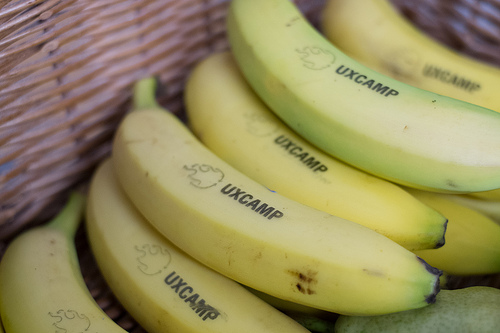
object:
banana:
[114, 76, 442, 313]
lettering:
[218, 183, 285, 221]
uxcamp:
[331, 63, 397, 103]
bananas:
[183, 55, 444, 252]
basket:
[0, 0, 232, 239]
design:
[295, 46, 339, 72]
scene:
[0, 0, 497, 333]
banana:
[229, 0, 499, 192]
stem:
[128, 74, 163, 109]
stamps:
[273, 134, 330, 174]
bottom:
[436, 217, 450, 251]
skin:
[204, 240, 275, 257]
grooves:
[53, 18, 139, 44]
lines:
[38, 31, 169, 63]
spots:
[294, 284, 316, 297]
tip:
[435, 277, 449, 302]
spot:
[427, 97, 442, 105]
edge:
[288, 1, 500, 115]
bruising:
[286, 262, 321, 296]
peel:
[350, 118, 474, 160]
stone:
[332, 286, 498, 332]